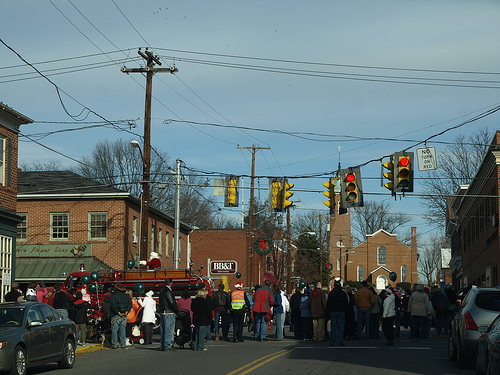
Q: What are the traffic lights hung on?
A: Black wires.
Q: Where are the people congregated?
A: On a street.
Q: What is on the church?
A: A spire.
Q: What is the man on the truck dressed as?
A: Santa Clause.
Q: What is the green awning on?
A: Lower level of a brick building.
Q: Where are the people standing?
A: At an intersection.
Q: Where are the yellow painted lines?
A: On the road.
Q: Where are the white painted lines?
A: On the road.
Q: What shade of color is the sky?
A: Blue.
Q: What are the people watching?
A: A parade.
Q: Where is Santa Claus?
A: On the fire truck.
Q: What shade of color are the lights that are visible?
A: Red.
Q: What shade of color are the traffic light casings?
A: Yellow and black.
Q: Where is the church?
A: Behind the intersection.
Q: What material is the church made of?
A: Bricks.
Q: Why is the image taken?
A: Remembrance.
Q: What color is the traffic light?
A: Red.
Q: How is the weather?
A: Cloudy.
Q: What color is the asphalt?
A: Black.